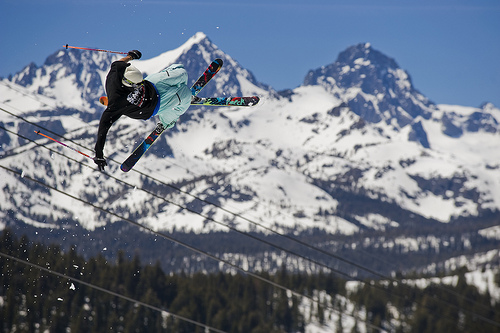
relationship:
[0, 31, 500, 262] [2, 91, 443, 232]
mountain covered in snow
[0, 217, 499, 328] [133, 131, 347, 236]
trees growing out snow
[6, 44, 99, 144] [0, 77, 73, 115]
mountain with snow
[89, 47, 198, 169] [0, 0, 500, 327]
person in air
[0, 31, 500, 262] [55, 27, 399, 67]
mountain has a top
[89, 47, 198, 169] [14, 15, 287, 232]
skier making a jump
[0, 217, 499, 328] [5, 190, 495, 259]
trees in background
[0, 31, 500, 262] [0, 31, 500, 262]
mountain on mountain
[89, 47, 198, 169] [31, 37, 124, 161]
person holding ski poles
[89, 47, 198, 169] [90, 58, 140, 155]
person wearing black top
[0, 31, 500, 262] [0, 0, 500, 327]
mountain in background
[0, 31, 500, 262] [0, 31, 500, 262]
mountain in mountain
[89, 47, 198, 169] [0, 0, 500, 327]
skier in air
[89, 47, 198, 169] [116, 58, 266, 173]
person on skies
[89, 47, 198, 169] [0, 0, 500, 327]
person skies in the air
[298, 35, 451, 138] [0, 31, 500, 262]
mount in mountain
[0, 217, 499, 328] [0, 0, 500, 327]
cable in sky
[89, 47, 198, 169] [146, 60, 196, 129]
person wearing blue shorts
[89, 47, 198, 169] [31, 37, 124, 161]
skier has poles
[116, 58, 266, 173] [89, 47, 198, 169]
skis of skier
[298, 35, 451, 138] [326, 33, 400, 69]
mountain has peak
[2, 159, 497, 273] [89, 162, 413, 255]
trees near ridge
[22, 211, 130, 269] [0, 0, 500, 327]
snow in air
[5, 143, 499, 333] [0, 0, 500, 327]
cables in air